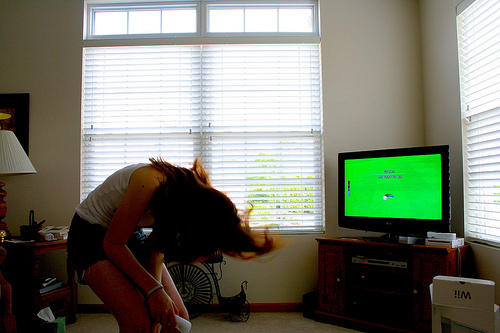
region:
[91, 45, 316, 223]
a window in the room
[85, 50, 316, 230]
blinds on the window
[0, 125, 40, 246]
a lamp on the end table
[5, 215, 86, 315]
a wooden end table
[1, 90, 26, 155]
a picture on the wall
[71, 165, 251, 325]
a woman bent over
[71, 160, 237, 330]
a woman in a white shirt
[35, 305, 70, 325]
a box of tissues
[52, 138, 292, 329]
she is bent over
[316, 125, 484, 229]
this is a TV set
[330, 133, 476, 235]
there is a golf game on the screen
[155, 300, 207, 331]
this is the Wii Controller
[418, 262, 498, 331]
this is the Wii box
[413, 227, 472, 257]
this is a Nintendo Wii console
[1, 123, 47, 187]
this is a white lampshade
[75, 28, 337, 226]
the blinds in the window are white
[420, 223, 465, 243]
a controller on a Wii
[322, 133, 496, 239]
the flat screen tv has a black bezel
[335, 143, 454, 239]
A black colored television.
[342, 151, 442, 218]
A green television screen.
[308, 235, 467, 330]
Wooden piece of furniture.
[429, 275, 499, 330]
A brown cardboard box.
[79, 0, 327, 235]
A large bright window.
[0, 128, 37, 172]
A white colored lamp shade.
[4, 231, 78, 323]
A wood coffee table.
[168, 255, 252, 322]
A black colored decoration.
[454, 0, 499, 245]
White colored window blinds.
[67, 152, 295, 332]
A young human female.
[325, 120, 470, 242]
THIS IS A MONITOR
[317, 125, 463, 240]
THIS IS A TELEVISION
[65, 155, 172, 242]
THE TANK TOP IS WHITE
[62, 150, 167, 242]
THE GIRL IS WEARING A TANK TOP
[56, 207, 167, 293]
THE GIRL'S SHORTS ARE BLACK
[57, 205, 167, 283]
THE GIRL IS WEARING SHORTS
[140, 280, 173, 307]
THE GIRL IS WEARING A BRACELET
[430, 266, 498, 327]
THIS IS A WII BOX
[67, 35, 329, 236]
THE BLINDS ARE WHITE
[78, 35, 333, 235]
THE BLINDS ARE DOWN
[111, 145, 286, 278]
the girl has brown hair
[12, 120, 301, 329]
the girl is playing Wii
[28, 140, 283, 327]
the girl is bent over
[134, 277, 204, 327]
Wii remote strapped to wrist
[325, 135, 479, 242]
television screen is green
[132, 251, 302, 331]
fan under the window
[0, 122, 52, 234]
lamp has a white lampshade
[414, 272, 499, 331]
box for the Wii is opened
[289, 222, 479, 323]
tv is on a brown wooden entertainment stand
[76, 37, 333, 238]
large double window covered with mini blinds